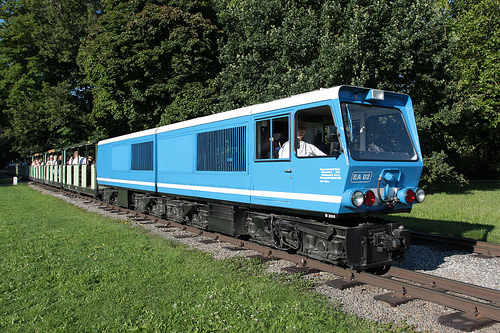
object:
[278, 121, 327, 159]
man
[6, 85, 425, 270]
train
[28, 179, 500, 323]
tracks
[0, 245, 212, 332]
grass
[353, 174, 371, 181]
numbers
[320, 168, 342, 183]
lettering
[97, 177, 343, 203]
stripe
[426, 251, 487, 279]
gravel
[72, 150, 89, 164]
people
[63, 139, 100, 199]
cars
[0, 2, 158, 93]
trees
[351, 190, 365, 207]
headlights